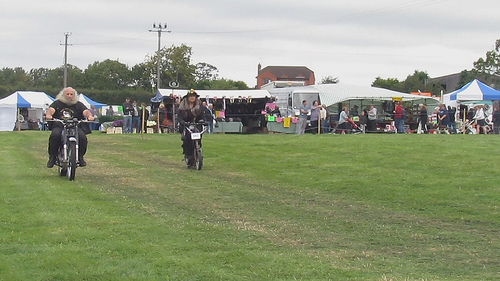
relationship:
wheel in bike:
[67, 140, 78, 180] [47, 113, 98, 178]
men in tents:
[27, 79, 260, 175] [211, 76, 433, 110]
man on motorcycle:
[43, 83, 98, 168] [39, 115, 99, 179]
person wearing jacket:
[167, 88, 225, 156] [175, 88, 205, 135]